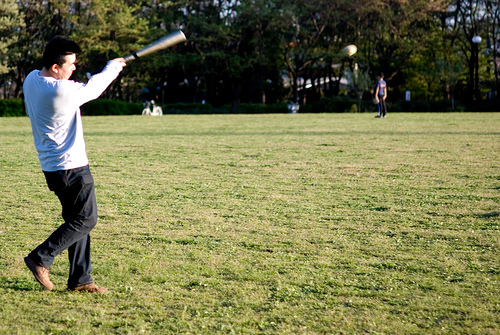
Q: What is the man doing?
A: Swinging a bat.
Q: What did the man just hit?
A: Ball.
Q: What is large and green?
A: The field.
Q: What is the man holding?
A: A bat.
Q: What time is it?
A: Afternoon.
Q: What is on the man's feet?
A: Shoes.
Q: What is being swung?
A: The bat.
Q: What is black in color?
A: The pants.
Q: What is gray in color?
A: The shirt.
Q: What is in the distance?
A: Trees.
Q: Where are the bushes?
A: Near the trees.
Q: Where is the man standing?
A: On the grass.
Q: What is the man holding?
A: A baseball bat.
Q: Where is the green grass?
A: On the ground.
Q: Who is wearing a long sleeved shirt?
A: The man.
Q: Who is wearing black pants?
A: The man.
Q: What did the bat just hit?
A: The ball.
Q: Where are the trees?
A: Next to the field.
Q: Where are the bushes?
A: In front of the trees.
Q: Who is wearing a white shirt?
A: The man.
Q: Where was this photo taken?
A: On a field.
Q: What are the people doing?
A: Playing.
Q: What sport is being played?
A: Baseball.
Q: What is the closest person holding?
A: A bat.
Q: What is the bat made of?
A: Metal.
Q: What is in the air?
A: A ball.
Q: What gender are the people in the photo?
A: Male.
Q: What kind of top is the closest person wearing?
A: A sweater.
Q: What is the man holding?
A: A bat.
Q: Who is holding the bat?
A: A man.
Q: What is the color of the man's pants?
A: Black.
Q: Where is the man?
A: In the park.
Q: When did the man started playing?
A: Just now.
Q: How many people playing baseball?
A: One.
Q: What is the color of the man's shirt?
A: Gray.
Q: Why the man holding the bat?
A: To play.